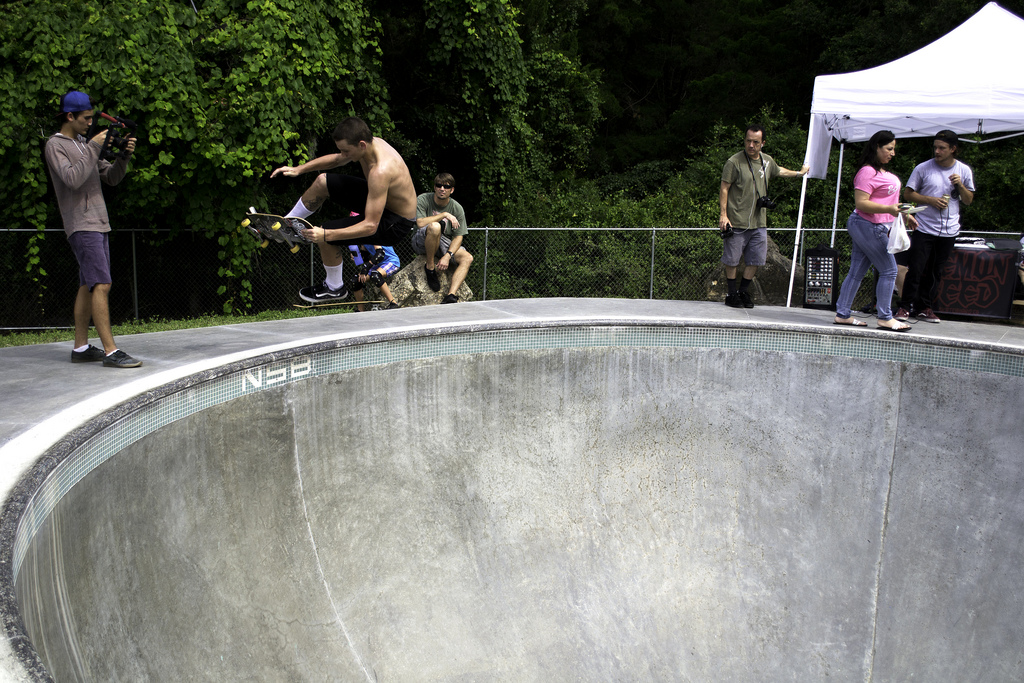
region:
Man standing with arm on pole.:
[714, 114, 801, 307]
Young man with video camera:
[41, 78, 163, 385]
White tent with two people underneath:
[799, 0, 1022, 340]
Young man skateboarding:
[242, 107, 420, 301]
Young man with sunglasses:
[414, 164, 476, 302]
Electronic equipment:
[796, 227, 842, 323]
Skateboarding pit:
[16, 326, 849, 678]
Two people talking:
[836, 123, 972, 324]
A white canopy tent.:
[782, 0, 1021, 358]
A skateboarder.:
[246, 133, 459, 349]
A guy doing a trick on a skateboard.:
[258, 138, 421, 306]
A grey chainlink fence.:
[5, 221, 1021, 330]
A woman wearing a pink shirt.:
[833, 141, 906, 350]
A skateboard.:
[230, 202, 325, 251]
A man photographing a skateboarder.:
[52, 116, 429, 333]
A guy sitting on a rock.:
[400, 162, 481, 311]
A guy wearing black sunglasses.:
[400, 173, 476, 284]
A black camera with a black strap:
[738, 157, 784, 221]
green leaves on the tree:
[411, 47, 497, 102]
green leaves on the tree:
[243, 59, 381, 187]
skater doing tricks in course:
[226, 115, 424, 322]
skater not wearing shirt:
[275, 123, 422, 247]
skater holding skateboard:
[236, 108, 434, 321]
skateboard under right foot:
[228, 196, 323, 266]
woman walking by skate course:
[820, 113, 919, 347]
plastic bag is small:
[876, 213, 915, 267]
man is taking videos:
[42, 84, 172, 378]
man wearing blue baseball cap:
[54, 88, 92, 115]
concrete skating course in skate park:
[10, 289, 1017, 676]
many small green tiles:
[7, 318, 1020, 595]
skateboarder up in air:
[232, 110, 426, 311]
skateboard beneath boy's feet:
[222, 195, 318, 260]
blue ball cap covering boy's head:
[57, 81, 97, 119]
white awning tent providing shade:
[775, 0, 1020, 313]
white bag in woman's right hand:
[883, 199, 910, 257]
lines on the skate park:
[248, 386, 732, 642]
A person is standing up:
[695, 115, 804, 312]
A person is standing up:
[843, 117, 900, 342]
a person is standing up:
[32, 74, 146, 372]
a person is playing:
[227, 105, 437, 312]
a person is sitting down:
[395, 165, 485, 301]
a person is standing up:
[709, 121, 811, 293]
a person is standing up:
[834, 125, 917, 321]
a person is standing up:
[886, 102, 1001, 330]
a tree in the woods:
[447, 7, 550, 230]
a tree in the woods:
[525, 39, 603, 211]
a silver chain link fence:
[6, 227, 940, 304]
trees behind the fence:
[13, 6, 1007, 218]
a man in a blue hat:
[44, 88, 140, 358]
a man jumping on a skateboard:
[250, 139, 419, 302]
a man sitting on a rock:
[411, 171, 487, 288]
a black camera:
[758, 187, 782, 210]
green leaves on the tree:
[454, 72, 524, 136]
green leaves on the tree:
[441, 48, 533, 140]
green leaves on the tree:
[232, 52, 322, 109]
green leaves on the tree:
[175, 90, 245, 168]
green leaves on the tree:
[282, 112, 336, 142]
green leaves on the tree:
[501, 203, 577, 249]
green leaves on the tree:
[476, 63, 614, 194]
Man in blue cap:
[41, 86, 190, 362]